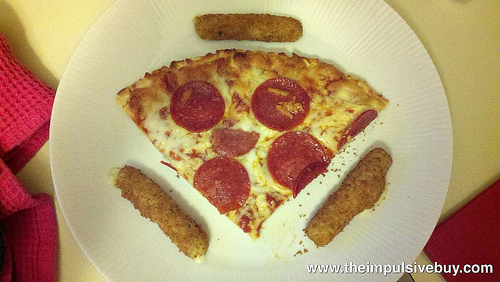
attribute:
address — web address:
[286, 241, 466, 275]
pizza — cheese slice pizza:
[116, 48, 388, 238]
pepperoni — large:
[254, 77, 307, 130]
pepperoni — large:
[172, 79, 223, 129]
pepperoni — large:
[268, 132, 319, 183]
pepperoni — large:
[195, 156, 248, 211]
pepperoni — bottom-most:
[262, 128, 333, 197]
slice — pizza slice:
[112, 47, 394, 247]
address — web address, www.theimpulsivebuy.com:
[300, 255, 497, 280]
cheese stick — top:
[189, 11, 299, 44]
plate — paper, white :
[51, 0, 460, 280]